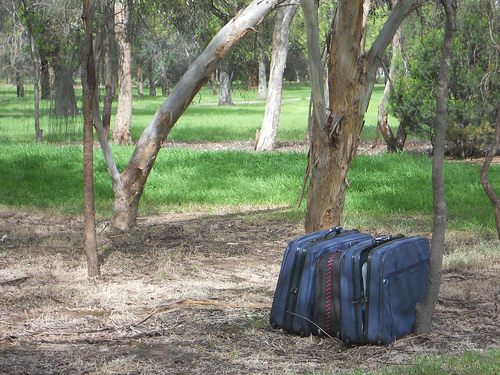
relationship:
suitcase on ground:
[288, 221, 418, 345] [150, 255, 239, 351]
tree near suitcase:
[277, 38, 439, 174] [288, 221, 418, 345]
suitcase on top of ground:
[288, 221, 418, 345] [150, 255, 239, 351]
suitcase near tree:
[288, 221, 418, 345] [277, 38, 439, 174]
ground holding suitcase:
[150, 255, 239, 351] [288, 221, 418, 345]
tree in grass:
[277, 38, 439, 174] [197, 155, 286, 207]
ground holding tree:
[150, 255, 239, 351] [277, 38, 439, 174]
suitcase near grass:
[288, 221, 418, 345] [197, 155, 286, 207]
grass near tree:
[197, 155, 286, 207] [277, 38, 439, 174]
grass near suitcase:
[197, 155, 286, 207] [288, 221, 418, 345]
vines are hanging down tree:
[343, 73, 420, 157] [277, 38, 439, 174]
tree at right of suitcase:
[393, 1, 465, 337] [288, 221, 418, 345]